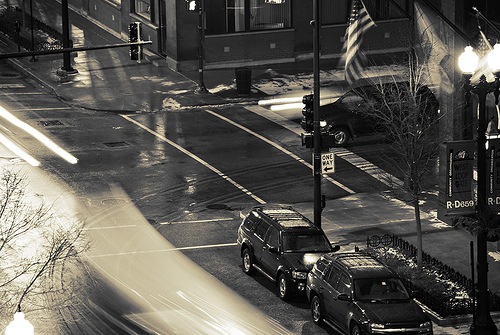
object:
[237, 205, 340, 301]
vehicle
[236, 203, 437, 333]
cars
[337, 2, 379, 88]
flag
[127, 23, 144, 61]
light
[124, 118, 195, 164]
lines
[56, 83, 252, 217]
road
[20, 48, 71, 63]
pole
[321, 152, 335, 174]
sign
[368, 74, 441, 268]
tree